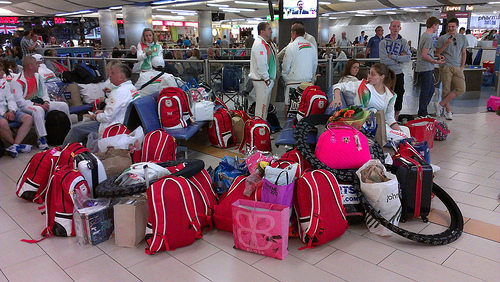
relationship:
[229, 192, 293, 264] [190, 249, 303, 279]
gift on ground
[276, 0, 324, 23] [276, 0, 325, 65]
tv on wall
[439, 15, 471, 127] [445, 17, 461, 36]
person has head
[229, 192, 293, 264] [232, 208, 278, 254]
bag has butterfly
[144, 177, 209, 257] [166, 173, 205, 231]
backpack has trim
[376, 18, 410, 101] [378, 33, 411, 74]
boy wearing sweatshirt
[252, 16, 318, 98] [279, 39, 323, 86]
men wearing jacket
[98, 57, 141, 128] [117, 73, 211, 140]
man on chair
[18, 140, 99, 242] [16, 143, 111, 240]
backpacks in group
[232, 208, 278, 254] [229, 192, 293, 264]
butterfly on bag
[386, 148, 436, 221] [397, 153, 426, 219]
suitcase has stripe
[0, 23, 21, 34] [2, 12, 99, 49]
flag on wall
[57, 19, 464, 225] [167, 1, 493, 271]
passengers at airport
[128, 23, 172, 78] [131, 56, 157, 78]
passenger has bag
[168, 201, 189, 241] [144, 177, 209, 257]
red on backpack